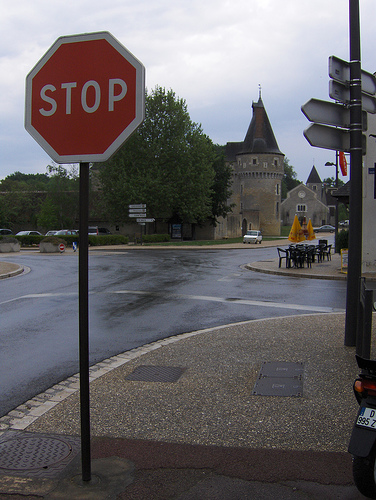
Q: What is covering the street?
A: Water.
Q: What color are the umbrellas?
A: Yellow.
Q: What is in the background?
A: Trees.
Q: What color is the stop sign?
A: Red and white.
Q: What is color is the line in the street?
A: White.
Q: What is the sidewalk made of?
A: Stones.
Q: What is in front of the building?
A: Trees.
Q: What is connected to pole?
A: Street signs.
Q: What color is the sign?
A: Red and white.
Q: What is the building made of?
A: Bricks.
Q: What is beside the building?
A: Tree.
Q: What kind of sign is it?
A: Stop.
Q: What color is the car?
A: White.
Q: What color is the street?
A: Black.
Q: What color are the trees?
A: Green.